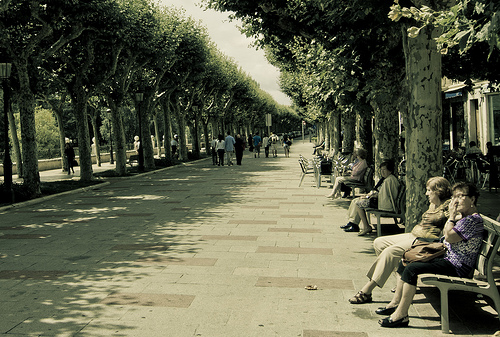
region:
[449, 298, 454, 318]
part of a bench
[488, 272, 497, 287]
edge of a bench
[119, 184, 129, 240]
part of a shadow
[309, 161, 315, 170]
edge of a bench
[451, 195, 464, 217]
face of a woman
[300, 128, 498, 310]
people sit on benches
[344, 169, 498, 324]
two woman sit on a bench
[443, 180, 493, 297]
woman wears a purple shirt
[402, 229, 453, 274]
a brown bag on a lap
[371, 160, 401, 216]
woman wears a white jacket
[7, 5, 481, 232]
trees on both sides of a pedestrian street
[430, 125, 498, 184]
people sits on sidewalk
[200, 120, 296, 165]
a group of people going down the street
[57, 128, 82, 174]
a woman wearing black cloths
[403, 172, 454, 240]
woman wears a brown shirt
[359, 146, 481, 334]
a couple sitting on a bench.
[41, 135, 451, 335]
a very long sidewalk.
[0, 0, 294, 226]
a long row of green trees.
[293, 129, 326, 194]
a bench near some trees.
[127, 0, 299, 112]
a hazy gray sky.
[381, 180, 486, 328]
a woman sitting on the ground.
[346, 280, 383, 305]
a left foot.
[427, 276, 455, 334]
a support on a bench.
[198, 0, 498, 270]
a leafy green tree.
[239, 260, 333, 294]
a colored brick.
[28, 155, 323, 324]
A long street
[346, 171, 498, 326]
People sitting on a bench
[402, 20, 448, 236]
A large tree trunk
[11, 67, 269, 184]
A line of trees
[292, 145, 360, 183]
A group of chairs on the street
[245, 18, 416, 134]
A line of green trees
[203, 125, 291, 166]
A group of people walking down the street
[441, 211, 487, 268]
Woman wearing a purple shirt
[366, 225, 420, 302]
A woman wearing tan pants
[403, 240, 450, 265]
A brown purse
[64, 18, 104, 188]
tree along the sidewalk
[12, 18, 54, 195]
tree along the sidewalk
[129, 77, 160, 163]
tree along the sidewalk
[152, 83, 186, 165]
tree along the sidewalk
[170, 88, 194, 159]
tree along the sidewalk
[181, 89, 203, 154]
tree along the sidewalk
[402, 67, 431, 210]
tree along the sidewalk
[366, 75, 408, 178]
tree along the sidewalk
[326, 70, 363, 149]
tree along the sidewalk